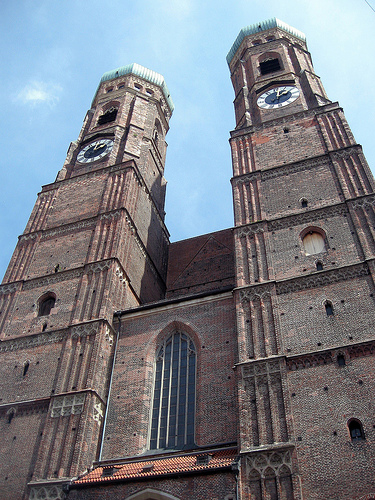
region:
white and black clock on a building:
[252, 77, 304, 112]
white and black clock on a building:
[73, 136, 115, 168]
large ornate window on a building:
[135, 315, 202, 455]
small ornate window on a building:
[35, 289, 56, 319]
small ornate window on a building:
[345, 413, 366, 449]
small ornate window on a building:
[321, 297, 333, 320]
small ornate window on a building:
[300, 223, 328, 258]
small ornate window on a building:
[298, 196, 307, 209]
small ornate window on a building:
[18, 359, 30, 381]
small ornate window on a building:
[3, 406, 15, 425]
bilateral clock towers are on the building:
[3, 17, 370, 498]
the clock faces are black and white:
[70, 83, 297, 162]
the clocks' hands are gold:
[71, 84, 300, 164]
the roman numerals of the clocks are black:
[73, 86, 300, 163]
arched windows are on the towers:
[90, 48, 288, 132]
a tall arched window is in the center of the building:
[147, 316, 204, 456]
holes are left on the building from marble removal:
[268, 195, 374, 455]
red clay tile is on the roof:
[72, 442, 237, 485]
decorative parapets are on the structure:
[17, 88, 374, 378]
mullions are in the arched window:
[139, 305, 205, 455]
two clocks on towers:
[63, 97, 324, 176]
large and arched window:
[138, 336, 202, 465]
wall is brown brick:
[54, 165, 358, 493]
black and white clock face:
[258, 82, 298, 117]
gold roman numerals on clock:
[256, 87, 292, 107]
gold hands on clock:
[252, 78, 303, 126]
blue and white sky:
[5, 43, 68, 133]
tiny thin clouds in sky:
[6, 58, 64, 130]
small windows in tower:
[37, 269, 71, 346]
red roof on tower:
[95, 455, 229, 472]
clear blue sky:
[40, 10, 206, 56]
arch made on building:
[295, 225, 330, 255]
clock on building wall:
[256, 85, 304, 106]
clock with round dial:
[77, 137, 111, 164]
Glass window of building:
[155, 336, 190, 443]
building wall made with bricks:
[298, 384, 323, 431]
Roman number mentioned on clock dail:
[287, 86, 299, 104]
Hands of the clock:
[93, 139, 104, 151]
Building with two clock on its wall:
[72, 83, 306, 164]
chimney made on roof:
[195, 451, 212, 464]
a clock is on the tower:
[76, 137, 112, 162]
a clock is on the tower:
[254, 84, 300, 109]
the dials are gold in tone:
[90, 137, 105, 152]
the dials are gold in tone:
[275, 86, 290, 101]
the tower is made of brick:
[5, 80, 369, 496]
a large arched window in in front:
[147, 316, 203, 458]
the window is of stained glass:
[146, 318, 202, 448]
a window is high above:
[32, 289, 59, 320]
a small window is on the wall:
[342, 415, 367, 446]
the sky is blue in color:
[1, 2, 373, 272]